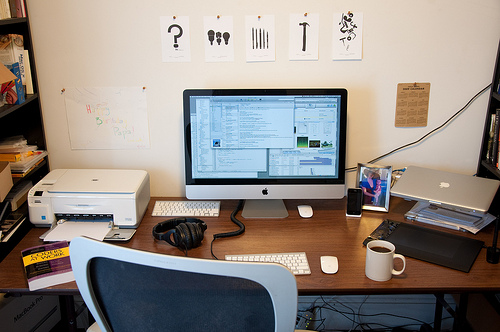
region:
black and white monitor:
[176, 87, 365, 217]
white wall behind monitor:
[380, 5, 447, 67]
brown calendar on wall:
[379, 58, 444, 145]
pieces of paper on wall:
[151, 10, 373, 92]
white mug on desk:
[373, 236, 395, 276]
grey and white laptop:
[387, 160, 497, 202]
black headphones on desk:
[156, 207, 198, 252]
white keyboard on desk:
[204, 244, 304, 278]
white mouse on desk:
[310, 244, 337, 284]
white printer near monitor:
[40, 170, 138, 252]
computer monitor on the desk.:
[176, 83, 350, 223]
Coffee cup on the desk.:
[361, 235, 408, 286]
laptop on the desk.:
[385, 155, 495, 221]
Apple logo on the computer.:
[430, 176, 450, 186]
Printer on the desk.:
[20, 150, 155, 241]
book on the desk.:
[10, 232, 75, 287]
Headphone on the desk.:
[146, 210, 206, 251]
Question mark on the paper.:
[156, 11, 191, 62]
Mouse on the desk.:
[315, 248, 341, 275]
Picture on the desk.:
[352, 155, 392, 215]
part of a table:
[455, 273, 470, 286]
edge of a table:
[286, 252, 345, 307]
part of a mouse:
[331, 264, 348, 278]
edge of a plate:
[312, 252, 334, 270]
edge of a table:
[338, 257, 343, 284]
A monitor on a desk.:
[183, 85, 348, 220]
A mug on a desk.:
[365, 236, 406, 282]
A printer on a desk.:
[27, 168, 152, 243]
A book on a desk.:
[20, 237, 75, 292]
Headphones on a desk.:
[151, 214, 208, 251]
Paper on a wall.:
[158, 10, 363, 62]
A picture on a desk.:
[356, 161, 391, 213]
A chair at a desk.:
[68, 233, 295, 329]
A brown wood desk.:
[1, 195, 498, 294]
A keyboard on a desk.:
[150, 198, 223, 218]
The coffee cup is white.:
[353, 234, 418, 287]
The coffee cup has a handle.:
[359, 232, 410, 290]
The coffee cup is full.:
[354, 230, 409, 282]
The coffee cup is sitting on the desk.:
[0, 160, 499, 298]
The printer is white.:
[9, 146, 156, 258]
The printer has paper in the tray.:
[14, 143, 154, 255]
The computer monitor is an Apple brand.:
[172, 75, 348, 220]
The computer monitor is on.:
[161, 70, 341, 230]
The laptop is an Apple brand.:
[385, 157, 496, 224]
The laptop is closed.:
[372, 146, 499, 224]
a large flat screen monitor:
[180, 85, 349, 202]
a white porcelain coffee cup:
[361, 237, 409, 281]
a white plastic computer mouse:
[318, 253, 336, 276]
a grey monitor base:
[239, 201, 292, 218]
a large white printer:
[21, 168, 153, 248]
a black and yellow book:
[13, 237, 84, 297]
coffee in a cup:
[374, 240, 391, 254]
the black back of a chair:
[88, 256, 274, 326]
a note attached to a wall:
[397, 80, 432, 130]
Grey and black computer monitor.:
[181, 84, 350, 219]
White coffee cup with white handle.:
[363, 239, 405, 282]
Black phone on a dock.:
[345, 185, 364, 217]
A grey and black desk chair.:
[68, 234, 298, 330]